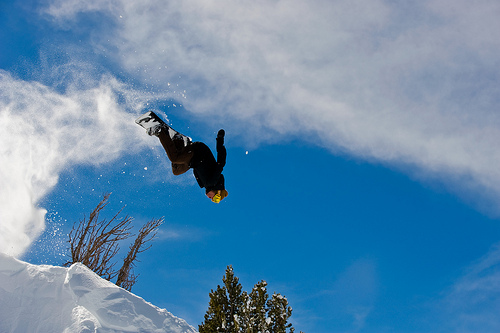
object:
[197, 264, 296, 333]
leaves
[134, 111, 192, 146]
snow board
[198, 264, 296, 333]
tree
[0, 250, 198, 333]
snow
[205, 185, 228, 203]
head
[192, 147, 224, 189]
jacket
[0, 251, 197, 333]
ground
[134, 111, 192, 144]
snowboarder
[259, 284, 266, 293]
snow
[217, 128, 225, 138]
glove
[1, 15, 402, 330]
outside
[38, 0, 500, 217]
smoke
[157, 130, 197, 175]
pants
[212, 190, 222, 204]
goggles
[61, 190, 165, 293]
branches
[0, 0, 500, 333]
sky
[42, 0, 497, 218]
clouds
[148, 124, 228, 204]
person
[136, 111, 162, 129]
snow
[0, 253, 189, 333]
hill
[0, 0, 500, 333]
air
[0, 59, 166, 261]
snow